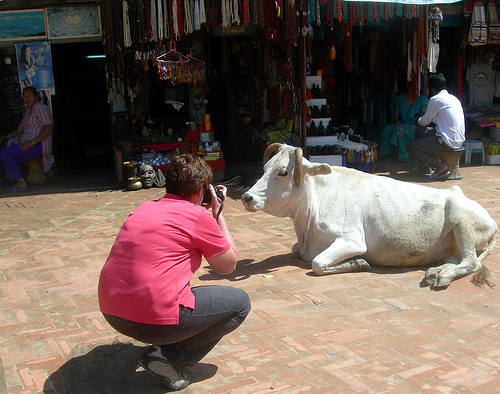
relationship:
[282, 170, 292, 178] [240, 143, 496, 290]
eye on animal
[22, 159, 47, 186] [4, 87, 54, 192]
stool on lady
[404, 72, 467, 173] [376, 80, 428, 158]
man and woman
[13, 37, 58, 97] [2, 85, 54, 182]
artwork above woman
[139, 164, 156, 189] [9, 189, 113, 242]
mask on ground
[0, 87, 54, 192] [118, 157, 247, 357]
lady with shirt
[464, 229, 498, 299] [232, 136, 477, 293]
tail of cow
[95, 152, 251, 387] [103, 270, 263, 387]
man wearing pants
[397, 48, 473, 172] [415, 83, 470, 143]
man wearing shirt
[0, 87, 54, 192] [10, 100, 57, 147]
lady wearing shirt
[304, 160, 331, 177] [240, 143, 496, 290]
ear of animal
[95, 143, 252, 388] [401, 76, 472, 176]
man on a man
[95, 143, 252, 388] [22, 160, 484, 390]
man on a sidewalk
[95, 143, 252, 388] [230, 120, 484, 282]
man taking picture animal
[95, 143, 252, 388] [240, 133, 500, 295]
man looking at cow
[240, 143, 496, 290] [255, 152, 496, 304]
animal laying on ground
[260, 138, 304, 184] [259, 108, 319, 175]
horns turned inward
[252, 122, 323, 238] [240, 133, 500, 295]
horns on cow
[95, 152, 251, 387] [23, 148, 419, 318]
man taking a picture